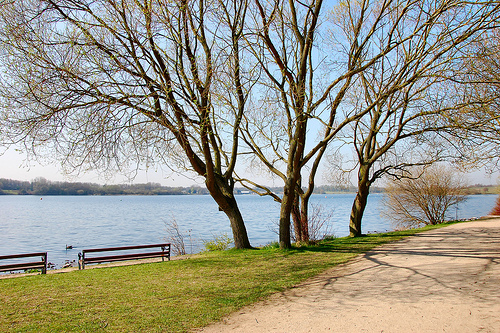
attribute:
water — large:
[0, 191, 497, 276]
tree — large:
[1, 1, 281, 260]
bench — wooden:
[78, 242, 173, 269]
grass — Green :
[0, 218, 467, 331]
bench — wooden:
[0, 252, 45, 276]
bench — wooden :
[72, 240, 171, 268]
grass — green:
[13, 230, 340, 312]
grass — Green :
[12, 227, 418, 328]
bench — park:
[81, 244, 216, 278]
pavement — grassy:
[220, 215, 499, 330]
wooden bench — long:
[1, 251, 47, 276]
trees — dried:
[79, 0, 421, 237]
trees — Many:
[62, 158, 184, 218]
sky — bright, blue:
[235, 38, 430, 140]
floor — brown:
[381, 250, 453, 312]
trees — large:
[6, 3, 250, 253]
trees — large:
[244, 10, 298, 249]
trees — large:
[294, 32, 314, 242]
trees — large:
[346, 0, 416, 244]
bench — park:
[0, 243, 52, 276]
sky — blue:
[6, 2, 476, 187]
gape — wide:
[77, 242, 170, 259]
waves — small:
[3, 193, 499, 272]